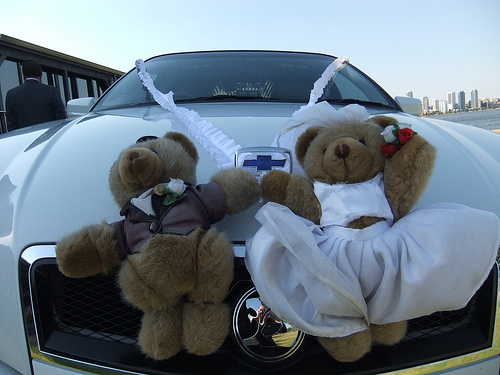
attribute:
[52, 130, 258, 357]
bear — TEDDY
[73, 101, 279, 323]
bear — stuffed